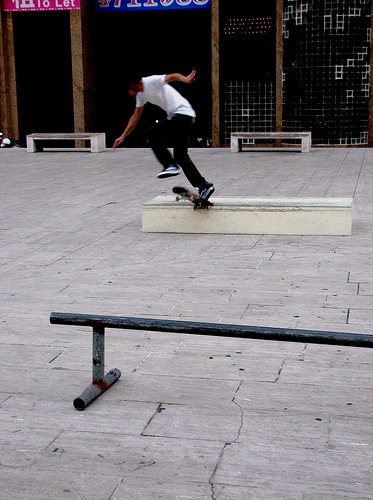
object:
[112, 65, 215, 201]
young man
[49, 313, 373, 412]
rail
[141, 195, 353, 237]
ledge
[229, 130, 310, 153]
bench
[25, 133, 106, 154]
bench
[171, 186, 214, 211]
skateboard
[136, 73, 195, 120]
shirt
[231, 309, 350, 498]
crack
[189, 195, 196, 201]
wheels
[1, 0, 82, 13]
sign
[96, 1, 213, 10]
sign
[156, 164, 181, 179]
foot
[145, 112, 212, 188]
pants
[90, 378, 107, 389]
paint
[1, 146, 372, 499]
ground